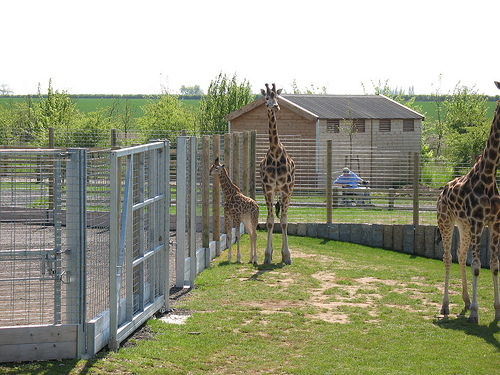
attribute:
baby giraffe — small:
[209, 158, 261, 267]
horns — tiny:
[260, 77, 275, 92]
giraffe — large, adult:
[258, 72, 298, 272]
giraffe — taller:
[257, 81, 297, 268]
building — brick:
[206, 86, 437, 208]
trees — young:
[3, 73, 491, 190]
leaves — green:
[3, 73, 490, 184]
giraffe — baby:
[204, 157, 260, 265]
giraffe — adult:
[256, 77, 294, 269]